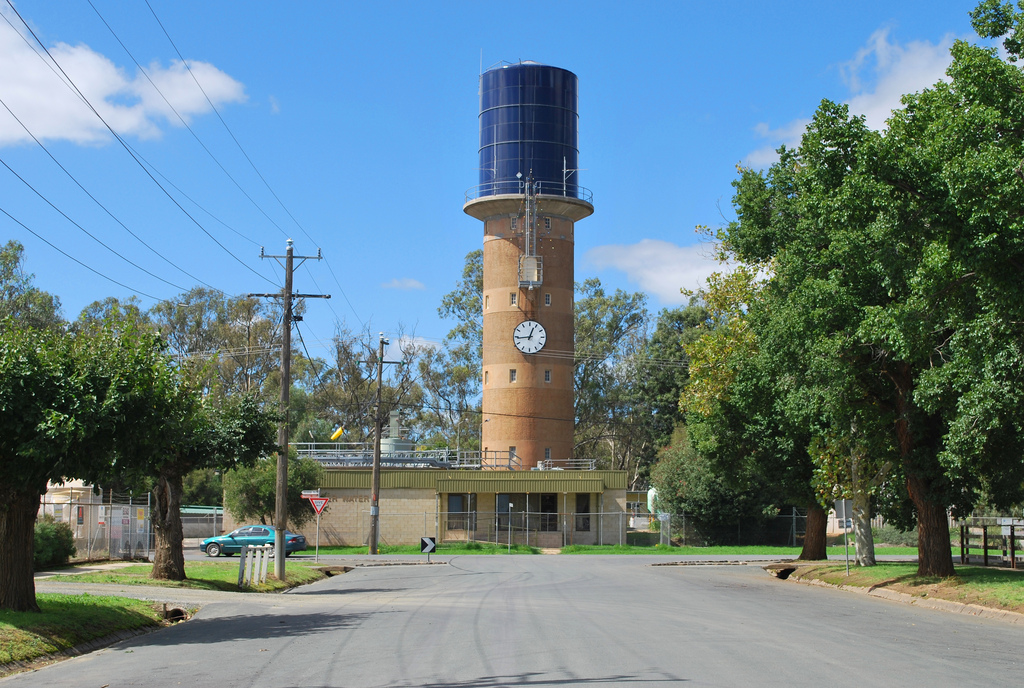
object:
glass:
[544, 370, 550, 383]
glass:
[447, 493, 463, 529]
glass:
[495, 493, 541, 513]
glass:
[528, 493, 558, 531]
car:
[200, 525, 306, 558]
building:
[222, 466, 625, 549]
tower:
[465, 58, 594, 203]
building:
[221, 58, 648, 546]